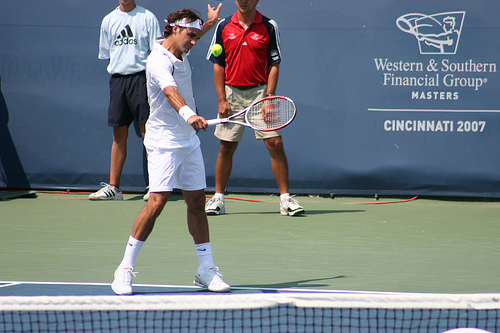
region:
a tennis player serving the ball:
[78, 4, 351, 327]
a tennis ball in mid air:
[201, 38, 236, 331]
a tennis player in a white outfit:
[110, 3, 317, 331]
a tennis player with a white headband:
[107, 2, 314, 323]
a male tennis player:
[82, 1, 362, 328]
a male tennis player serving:
[87, 3, 327, 328]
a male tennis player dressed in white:
[94, 5, 314, 330]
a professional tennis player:
[85, 3, 302, 332]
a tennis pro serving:
[91, 0, 313, 327]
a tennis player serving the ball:
[79, 1, 289, 323]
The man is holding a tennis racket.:
[101, 3, 298, 302]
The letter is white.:
[403, 84, 420, 107]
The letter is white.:
[417, 88, 427, 105]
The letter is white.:
[423, 86, 433, 102]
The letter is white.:
[431, 84, 441, 101]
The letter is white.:
[437, 88, 447, 103]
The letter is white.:
[443, 88, 453, 105]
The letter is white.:
[451, 88, 461, 103]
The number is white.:
[455, 118, 465, 134]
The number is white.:
[477, 118, 488, 135]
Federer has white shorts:
[122, 131, 205, 202]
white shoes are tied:
[100, 256, 245, 306]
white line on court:
[76, 263, 261, 305]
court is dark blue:
[152, 306, 261, 331]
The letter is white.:
[371, 51, 388, 71]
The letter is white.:
[438, 55, 449, 75]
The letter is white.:
[379, 68, 392, 87]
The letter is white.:
[439, 69, 456, 91]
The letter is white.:
[379, 115, 391, 135]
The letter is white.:
[393, 117, 405, 137]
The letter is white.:
[413, 58, 425, 75]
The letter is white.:
[414, 117, 426, 138]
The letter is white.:
[425, 117, 436, 134]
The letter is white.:
[433, 117, 445, 136]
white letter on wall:
[373, 55, 387, 74]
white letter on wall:
[385, 58, 393, 71]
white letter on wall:
[392, 59, 399, 71]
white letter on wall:
[397, 59, 404, 71]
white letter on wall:
[381, 69, 390, 86]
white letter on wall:
[393, 73, 405, 88]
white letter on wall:
[382, 116, 393, 133]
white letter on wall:
[393, 118, 404, 132]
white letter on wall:
[403, 116, 412, 133]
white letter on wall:
[424, 119, 435, 133]